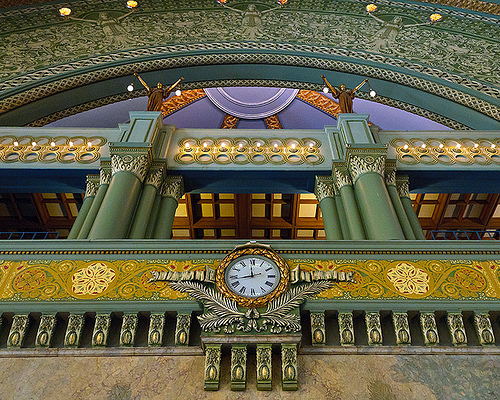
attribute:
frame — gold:
[224, 251, 280, 293]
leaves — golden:
[165, 275, 336, 335]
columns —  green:
[87, 153, 169, 240]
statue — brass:
[304, 59, 372, 123]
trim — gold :
[61, 130, 421, 216]